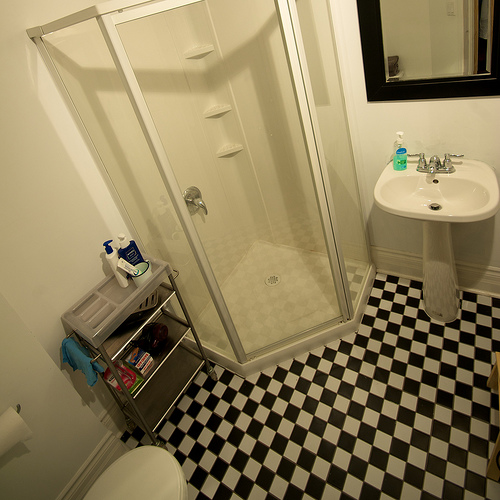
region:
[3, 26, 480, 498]
a shower room with a sink and toilet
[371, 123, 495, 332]
a pedestal sink in a shower room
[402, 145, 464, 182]
a faucet on a sink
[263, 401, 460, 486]
a black and white flooring on the shower room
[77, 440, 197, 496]
a white toilet with the lid close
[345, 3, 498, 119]
a mirror on the wall above the sink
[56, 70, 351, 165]
a glass shower in the shower room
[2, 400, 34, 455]
a role of white toilet paper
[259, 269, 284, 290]
a drainage in the shower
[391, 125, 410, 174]
a soap dispenser on the sink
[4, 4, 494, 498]
A bathroom scene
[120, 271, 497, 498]
The floor has a checkered pattern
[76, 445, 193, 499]
This is a commode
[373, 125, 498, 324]
A pedestal sink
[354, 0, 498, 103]
A mirror is on the wall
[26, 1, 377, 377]
This is a shower stall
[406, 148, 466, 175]
The sink's fixtures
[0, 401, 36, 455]
A roll of toilet paper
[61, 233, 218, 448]
A hand cart is beside the shower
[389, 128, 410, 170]
A bottle of hand soap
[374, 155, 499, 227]
a white porcelain bathroom sink basin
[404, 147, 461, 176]
a chrome bathroom faucet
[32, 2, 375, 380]
a white shower stall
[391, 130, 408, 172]
a bottle of hand soap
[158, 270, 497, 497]
a brown and white checkered floor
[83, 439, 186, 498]
a white plastic toilet seat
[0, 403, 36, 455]
a roll of toilet paper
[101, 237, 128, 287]
a bottle of lotion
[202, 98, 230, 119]
a small wall shelf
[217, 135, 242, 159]
a small wall shelf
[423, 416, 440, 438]
part of a floor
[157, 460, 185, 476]
part of a toilet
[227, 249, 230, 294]
part of a window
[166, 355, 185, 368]
part of a trolley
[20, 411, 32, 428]
edge of a tissue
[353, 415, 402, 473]
part of the floor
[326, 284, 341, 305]
edge of a window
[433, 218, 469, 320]
edge of a sink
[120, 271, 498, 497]
black and white tile floor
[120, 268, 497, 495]
a checkered bathroom floor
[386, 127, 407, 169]
teal hand soap on a sink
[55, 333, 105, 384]
a blue wash cloth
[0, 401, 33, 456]
toilet paper on a rack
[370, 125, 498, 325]
bathroom sink with soap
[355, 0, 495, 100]
mirror with black frames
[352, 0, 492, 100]
bathroom mirror with black frames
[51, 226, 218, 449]
a rolling bathroom caddy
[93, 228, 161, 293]
lotion and toothpaste in a cup